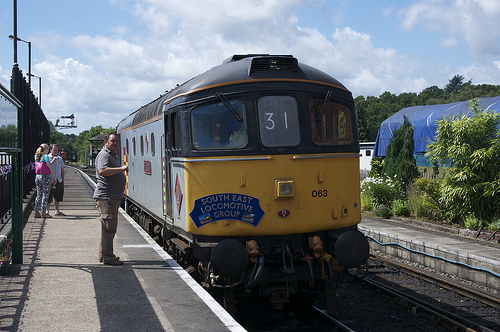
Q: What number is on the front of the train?
A: 31.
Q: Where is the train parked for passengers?
A: The station.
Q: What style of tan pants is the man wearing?
A: Khaki.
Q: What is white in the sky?
A: Clouds.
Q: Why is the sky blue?
A: The atmosphere makes it blue.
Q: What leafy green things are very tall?
A: Trees.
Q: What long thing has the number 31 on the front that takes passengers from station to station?
A: A train.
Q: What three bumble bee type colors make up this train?
A: Yellow, black and silver.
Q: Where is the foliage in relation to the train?
A: To the right.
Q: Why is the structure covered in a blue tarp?
A: To shield it from weather.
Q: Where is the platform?
A: To the left of the train.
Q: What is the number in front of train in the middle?
A: 31.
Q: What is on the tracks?
A: Train.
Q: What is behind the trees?
A: Blue building.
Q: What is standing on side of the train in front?
A: A man.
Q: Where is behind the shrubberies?
A: Building.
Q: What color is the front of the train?
A: Yellow.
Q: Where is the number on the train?
A: On the front.